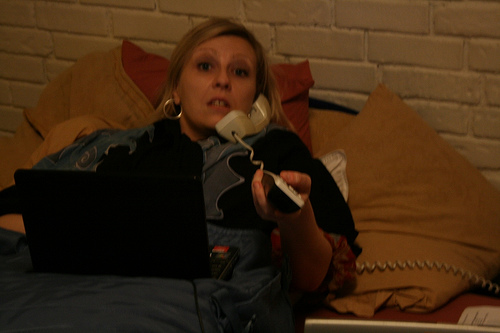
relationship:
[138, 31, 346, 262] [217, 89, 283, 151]
woman on phone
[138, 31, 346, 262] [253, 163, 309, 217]
woman holding remote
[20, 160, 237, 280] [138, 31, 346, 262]
computer on woman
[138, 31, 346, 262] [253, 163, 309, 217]
woman has remote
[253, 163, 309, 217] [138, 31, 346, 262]
remote on woman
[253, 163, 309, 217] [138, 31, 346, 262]
remote near woman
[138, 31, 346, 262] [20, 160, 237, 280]
woman on computer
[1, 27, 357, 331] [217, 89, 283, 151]
person using phone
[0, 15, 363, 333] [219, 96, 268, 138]
woman talking on phone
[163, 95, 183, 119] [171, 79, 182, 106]
hoop earring on ear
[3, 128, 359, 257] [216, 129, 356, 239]
design on shoulders